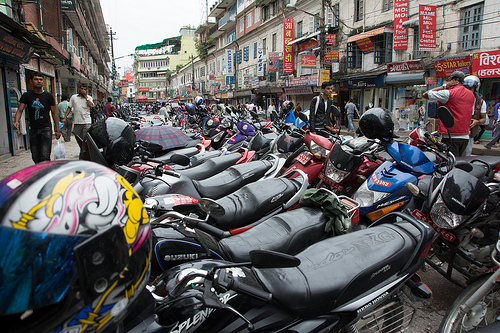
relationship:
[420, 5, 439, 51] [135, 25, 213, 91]
sign on building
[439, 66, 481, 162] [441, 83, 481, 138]
man wearing vest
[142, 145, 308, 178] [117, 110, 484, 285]
motorcycle in row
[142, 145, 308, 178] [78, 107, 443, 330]
motorcycle in row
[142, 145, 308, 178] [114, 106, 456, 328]
motorcycle in row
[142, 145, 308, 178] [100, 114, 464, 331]
motorcycle in row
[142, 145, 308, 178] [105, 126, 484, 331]
motorcycle in row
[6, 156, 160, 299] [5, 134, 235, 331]
helmet in foreground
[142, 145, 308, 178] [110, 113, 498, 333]
motorcycle in row